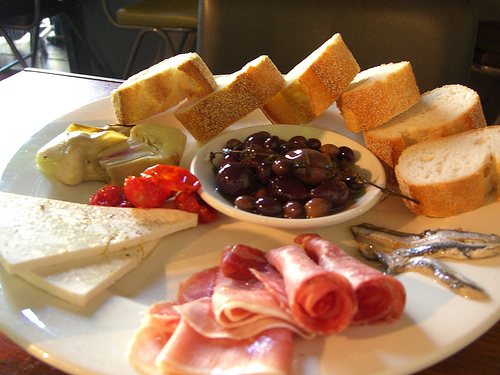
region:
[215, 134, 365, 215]
the olives are on a dish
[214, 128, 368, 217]
the olives are black in color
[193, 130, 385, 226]
the dish is white in color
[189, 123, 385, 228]
the dish is made of ceramic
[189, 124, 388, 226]
the dish is shiny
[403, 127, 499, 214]
a slice of bread is on the dish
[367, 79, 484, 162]
a slice of bread is on the dish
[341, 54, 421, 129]
a slice of bread is on the dish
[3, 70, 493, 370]
the dish is white in color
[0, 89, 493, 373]
the dish is made of ceramic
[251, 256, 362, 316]
meat on the plate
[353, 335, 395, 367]
the plate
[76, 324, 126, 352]
the plate is white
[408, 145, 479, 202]
bread on the plate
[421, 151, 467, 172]
the inside of the bread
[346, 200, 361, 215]
a bowl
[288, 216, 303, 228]
the bowl is white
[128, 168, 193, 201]
red fruit on the plate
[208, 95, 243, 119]
the crust of the bread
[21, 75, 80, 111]
a table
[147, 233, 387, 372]
rolled up sandwich meat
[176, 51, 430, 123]
slices of bread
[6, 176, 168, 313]
cheese for the sandwiches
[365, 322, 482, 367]
the edge of the plate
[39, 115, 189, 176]
mushrooms on the side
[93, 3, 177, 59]
a metal chair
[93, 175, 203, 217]
a side of sun dried tomatoes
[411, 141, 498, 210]
a piece of bread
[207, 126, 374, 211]
a bowl of water chesnuts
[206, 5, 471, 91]
the back of a chair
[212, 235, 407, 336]
rolled ham on a plate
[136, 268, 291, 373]
folded ham on a plate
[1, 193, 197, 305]
slices of white cheese on a plate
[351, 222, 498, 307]
sardines on a plate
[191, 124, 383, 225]
a white bowl full of olives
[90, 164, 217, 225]
dried tomatoes on a plate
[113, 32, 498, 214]
baguette bread chopped in loaves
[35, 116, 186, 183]
artichoke hearts on a plate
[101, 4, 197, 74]
a yellow chair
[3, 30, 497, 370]
a plate with bread and appetizers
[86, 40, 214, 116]
bread on the plate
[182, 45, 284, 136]
bread on the plate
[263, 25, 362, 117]
bread on the plate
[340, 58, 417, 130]
bread on the plate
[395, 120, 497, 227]
bread on the plate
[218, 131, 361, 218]
olives in a bowl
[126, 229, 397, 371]
meat on the plate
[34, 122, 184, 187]
artichoke hearts on the plate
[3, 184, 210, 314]
cheese on the plate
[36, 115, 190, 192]
artichoke hearts next to bread